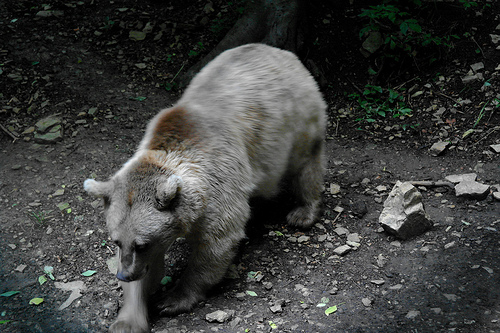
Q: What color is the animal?
A: Gray and brown.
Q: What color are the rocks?
A: Gray.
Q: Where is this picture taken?
A: In the woods.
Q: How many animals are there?
A: One.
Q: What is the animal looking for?
A: Food.